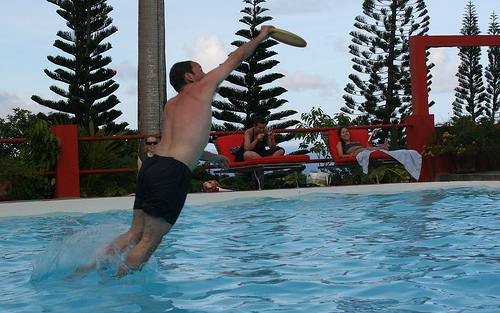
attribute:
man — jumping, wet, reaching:
[138, 80, 201, 253]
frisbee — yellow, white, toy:
[265, 22, 330, 55]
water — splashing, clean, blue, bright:
[59, 228, 126, 276]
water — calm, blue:
[43, 216, 493, 276]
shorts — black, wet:
[145, 161, 194, 199]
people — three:
[232, 120, 395, 175]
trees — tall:
[49, 18, 418, 130]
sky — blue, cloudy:
[181, 9, 467, 83]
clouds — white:
[193, 36, 246, 65]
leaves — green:
[92, 72, 114, 98]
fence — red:
[28, 113, 179, 184]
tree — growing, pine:
[228, 1, 285, 131]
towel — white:
[386, 145, 427, 176]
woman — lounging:
[327, 127, 372, 162]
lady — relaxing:
[244, 120, 286, 162]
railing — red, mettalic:
[32, 112, 135, 187]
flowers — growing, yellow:
[437, 131, 470, 153]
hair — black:
[169, 66, 183, 85]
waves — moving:
[12, 219, 205, 285]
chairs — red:
[220, 143, 401, 176]